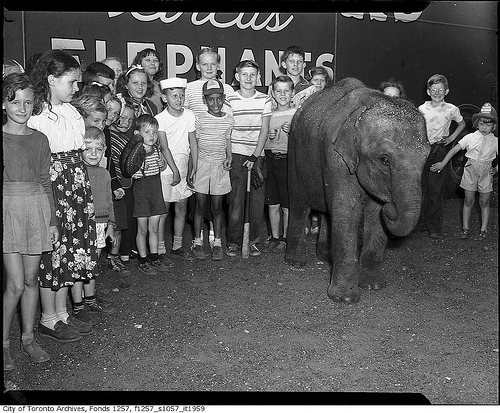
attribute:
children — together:
[0, 46, 495, 373]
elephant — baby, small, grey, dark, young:
[285, 76, 429, 316]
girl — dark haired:
[441, 93, 497, 239]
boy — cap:
[195, 78, 229, 265]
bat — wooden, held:
[239, 160, 254, 259]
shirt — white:
[30, 100, 95, 161]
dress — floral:
[33, 107, 96, 295]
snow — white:
[108, 291, 192, 357]